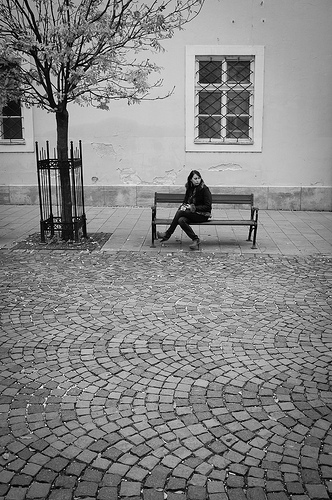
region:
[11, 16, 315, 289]
black and white photo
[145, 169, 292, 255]
pretty lady on a bench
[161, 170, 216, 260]
the lady is wearing black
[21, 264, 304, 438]
a paved brick road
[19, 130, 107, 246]
gate around the tree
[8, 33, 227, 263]
tree next to the bench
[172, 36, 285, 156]
a gated window on a wall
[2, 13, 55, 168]
a window behind the tree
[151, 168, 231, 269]
the lady is waiting on someone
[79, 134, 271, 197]
the wall is chipped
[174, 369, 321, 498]
The ground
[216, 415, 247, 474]
The ground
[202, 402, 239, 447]
The ground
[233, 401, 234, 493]
The ground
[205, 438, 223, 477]
The ground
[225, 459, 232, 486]
The ground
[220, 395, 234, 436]
The ground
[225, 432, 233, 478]
The ground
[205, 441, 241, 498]
The ground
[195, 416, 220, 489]
The ground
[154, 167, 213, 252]
woman sitting on bench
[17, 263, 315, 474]
arch-shaped brick road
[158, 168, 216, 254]
seated woman with legs crossed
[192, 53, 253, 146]
security wire on window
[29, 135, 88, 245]
security fencing around tree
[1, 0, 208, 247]
small tree with few leaves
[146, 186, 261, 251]
wood and iron bench on sidewalk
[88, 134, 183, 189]
cracks and gaps in building wall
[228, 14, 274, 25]
large holes in building wall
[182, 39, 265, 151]
six pane window in wall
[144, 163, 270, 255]
girl alone on a bench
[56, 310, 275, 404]
decorative design with bricks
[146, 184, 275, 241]
bench near a brick patio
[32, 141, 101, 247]
fence around a tree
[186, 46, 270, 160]
window with diagonal bars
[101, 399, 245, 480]
square bricks on a patio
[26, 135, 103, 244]
square metal fence for a sapling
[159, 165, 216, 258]
girl in jeans and high heels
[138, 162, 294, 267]
girl outside waiting on a bench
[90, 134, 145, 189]
damages stucco on side of building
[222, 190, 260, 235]
A bench in the photo.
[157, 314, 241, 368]
A cabro paved surface.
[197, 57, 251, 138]
A window in the photo.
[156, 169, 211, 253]
A young lady seated on a bench.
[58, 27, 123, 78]
leaves of a tree in the photo.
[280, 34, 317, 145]
Concrete wall in the photo.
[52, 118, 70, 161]
Tree trunk in the photo.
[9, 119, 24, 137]
Metal grills on the window.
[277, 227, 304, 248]
Blocks paved surface in the picture.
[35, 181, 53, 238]
Metal bars in the picture.